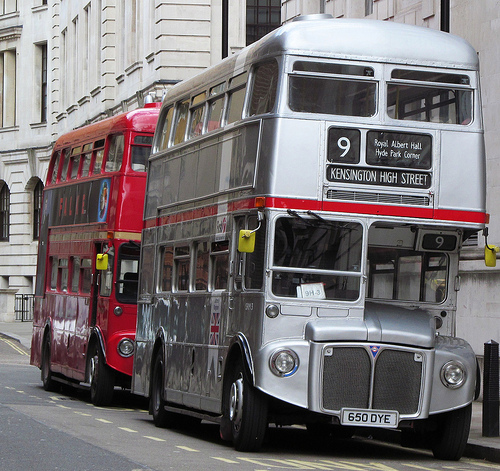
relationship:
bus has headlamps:
[149, 90, 485, 442] [279, 338, 463, 392]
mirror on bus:
[92, 245, 124, 288] [49, 124, 166, 391]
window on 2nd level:
[386, 65, 465, 120] [285, 33, 319, 50]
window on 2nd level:
[91, 139, 141, 171] [285, 33, 319, 50]